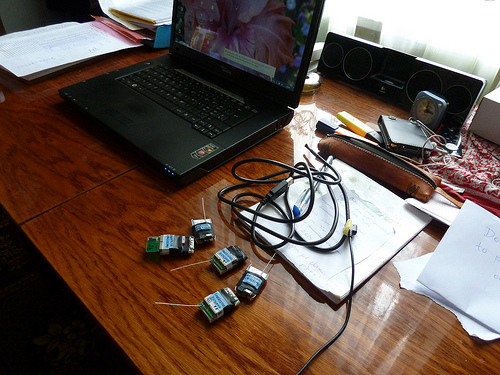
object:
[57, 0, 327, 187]
laptop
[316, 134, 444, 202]
case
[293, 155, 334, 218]
pen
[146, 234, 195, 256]
gizmo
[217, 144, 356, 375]
cable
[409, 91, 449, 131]
clock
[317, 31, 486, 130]
speaker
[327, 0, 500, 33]
sheers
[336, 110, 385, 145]
highlighter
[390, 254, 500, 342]
paper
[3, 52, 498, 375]
surface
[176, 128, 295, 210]
shadow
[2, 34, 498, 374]
desk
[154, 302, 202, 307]
straw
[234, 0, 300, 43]
flower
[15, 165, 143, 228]
crack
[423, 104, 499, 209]
cloth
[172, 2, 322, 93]
screen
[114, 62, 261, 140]
keyboard